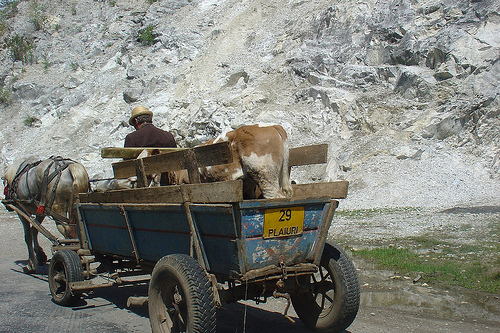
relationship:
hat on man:
[106, 96, 170, 138] [122, 105, 174, 149]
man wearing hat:
[122, 105, 174, 149] [106, 96, 170, 138]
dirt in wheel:
[369, 288, 498, 331] [144, 250, 215, 332]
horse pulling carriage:
[6, 153, 88, 271] [50, 140, 362, 327]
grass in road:
[350, 235, 498, 297] [1, 206, 499, 330]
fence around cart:
[99, 142, 349, 201] [44, 189, 362, 331]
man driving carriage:
[122, 105, 174, 149] [50, 140, 362, 327]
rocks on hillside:
[119, 68, 149, 102] [2, 1, 499, 199]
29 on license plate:
[279, 210, 290, 225] [261, 207, 303, 236]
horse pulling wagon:
[6, 153, 88, 271] [81, 152, 362, 330]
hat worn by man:
[124, 108, 162, 126] [122, 105, 174, 149]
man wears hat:
[122, 105, 174, 149] [124, 108, 162, 126]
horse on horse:
[6, 153, 88, 271] [6, 153, 88, 271]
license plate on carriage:
[261, 207, 303, 236] [50, 140, 362, 327]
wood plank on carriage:
[113, 142, 234, 179] [50, 140, 362, 327]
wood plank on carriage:
[73, 177, 243, 205] [50, 140, 362, 327]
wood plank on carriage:
[282, 139, 332, 166] [50, 140, 362, 327]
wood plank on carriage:
[286, 180, 351, 199] [50, 140, 362, 327]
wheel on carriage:
[144, 250, 215, 332] [50, 140, 362, 327]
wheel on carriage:
[282, 242, 360, 329] [50, 140, 362, 327]